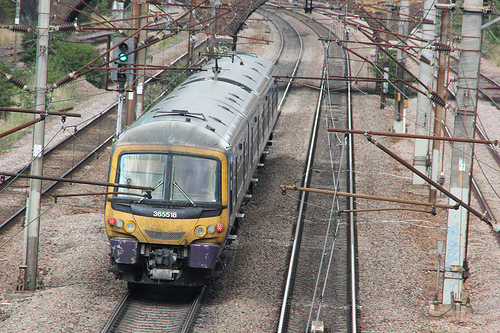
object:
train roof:
[127, 67, 259, 140]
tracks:
[292, 181, 358, 191]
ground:
[200, 323, 257, 329]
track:
[317, 97, 355, 105]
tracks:
[299, 166, 358, 174]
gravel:
[52, 305, 62, 315]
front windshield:
[114, 151, 218, 205]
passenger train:
[102, 51, 280, 302]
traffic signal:
[109, 36, 137, 86]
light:
[116, 63, 126, 71]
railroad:
[266, 215, 374, 329]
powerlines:
[19, 22, 54, 60]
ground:
[370, 273, 389, 286]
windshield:
[111, 156, 163, 203]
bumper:
[107, 238, 220, 268]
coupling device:
[138, 242, 187, 280]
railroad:
[107, 282, 205, 307]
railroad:
[263, 9, 304, 68]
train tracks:
[311, 26, 329, 28]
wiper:
[140, 179, 162, 202]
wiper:
[171, 180, 198, 205]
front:
[107, 144, 229, 289]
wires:
[311, 269, 320, 311]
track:
[304, 149, 356, 157]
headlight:
[107, 217, 116, 226]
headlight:
[215, 223, 223, 232]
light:
[117, 72, 126, 81]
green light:
[119, 52, 127, 61]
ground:
[16, 317, 36, 332]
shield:
[170, 157, 217, 205]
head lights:
[194, 226, 207, 238]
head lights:
[125, 222, 137, 233]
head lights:
[206, 225, 215, 234]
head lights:
[116, 219, 123, 229]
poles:
[376, 139, 489, 226]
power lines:
[376, 68, 411, 100]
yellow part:
[140, 222, 175, 234]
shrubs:
[56, 38, 65, 48]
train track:
[314, 28, 330, 30]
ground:
[393, 213, 422, 231]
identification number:
[153, 210, 177, 218]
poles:
[323, 128, 493, 145]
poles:
[44, 191, 146, 197]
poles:
[317, 39, 436, 50]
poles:
[0, 108, 82, 118]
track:
[99, 326, 206, 331]